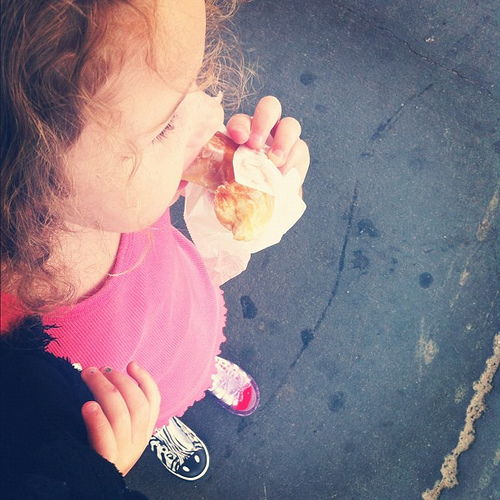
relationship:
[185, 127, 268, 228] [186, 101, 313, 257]
donut in hand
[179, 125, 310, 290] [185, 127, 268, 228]
wrapper around donut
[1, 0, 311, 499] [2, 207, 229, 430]
girl wearing shirt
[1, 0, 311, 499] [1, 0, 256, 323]
girl has hair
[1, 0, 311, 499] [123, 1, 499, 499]
girl on concrete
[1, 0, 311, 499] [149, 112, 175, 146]
girl has eye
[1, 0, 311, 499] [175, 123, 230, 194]
girl has mouth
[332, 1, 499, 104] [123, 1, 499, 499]
crack in concrete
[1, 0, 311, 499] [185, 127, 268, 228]
girl eating donut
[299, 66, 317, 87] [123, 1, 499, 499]
spot on concrete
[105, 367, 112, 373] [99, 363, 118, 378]
paint on fingernail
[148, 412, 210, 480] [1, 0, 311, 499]
shoes worn by girl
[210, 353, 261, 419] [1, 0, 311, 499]
shoe worn by girl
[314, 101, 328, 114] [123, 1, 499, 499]
spot on concrete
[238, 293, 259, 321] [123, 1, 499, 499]
spot on concrete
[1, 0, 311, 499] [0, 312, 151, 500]
girl holding stuffed toy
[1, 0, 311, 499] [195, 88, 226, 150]
girl has nose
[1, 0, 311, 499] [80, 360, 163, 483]
girl has right hand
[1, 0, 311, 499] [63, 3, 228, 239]
girl has face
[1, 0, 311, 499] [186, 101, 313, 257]
girl has left hand